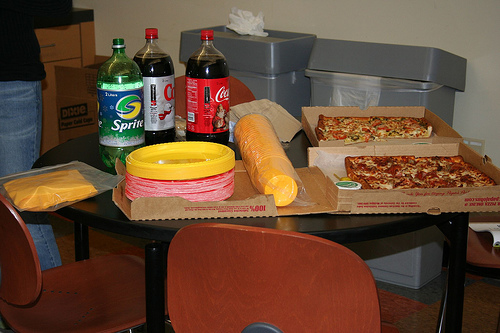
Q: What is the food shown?
A: Pizza.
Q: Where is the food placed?
A: Table.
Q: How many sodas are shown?
A: Three.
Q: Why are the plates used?
A: Hold food.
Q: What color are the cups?
A: Yellow.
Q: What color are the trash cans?
A: Gray.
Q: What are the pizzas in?
A: Boxes.